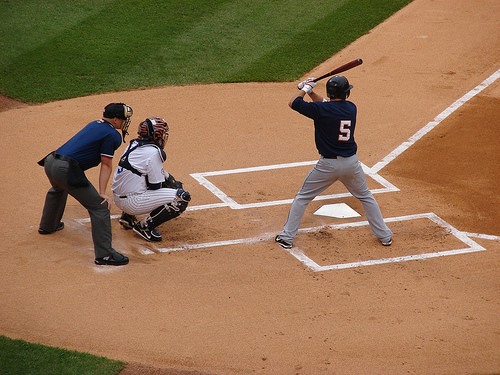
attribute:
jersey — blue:
[290, 96, 359, 159]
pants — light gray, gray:
[279, 152, 394, 247]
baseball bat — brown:
[304, 59, 366, 85]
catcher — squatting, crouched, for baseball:
[111, 114, 192, 244]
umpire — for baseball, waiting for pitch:
[34, 102, 133, 268]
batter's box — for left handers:
[274, 211, 488, 274]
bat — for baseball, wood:
[308, 57, 365, 84]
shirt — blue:
[290, 95, 359, 158]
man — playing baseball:
[35, 102, 132, 268]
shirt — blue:
[56, 117, 123, 171]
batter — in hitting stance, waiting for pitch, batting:
[272, 75, 395, 249]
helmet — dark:
[324, 74, 355, 101]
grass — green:
[0, 336, 132, 375]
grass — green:
[1, 1, 414, 109]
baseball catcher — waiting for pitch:
[111, 116, 191, 242]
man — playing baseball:
[272, 73, 394, 247]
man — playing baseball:
[111, 117, 194, 244]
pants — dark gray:
[37, 151, 113, 259]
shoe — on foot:
[273, 230, 293, 249]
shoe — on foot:
[378, 234, 395, 247]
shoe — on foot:
[118, 210, 138, 230]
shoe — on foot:
[131, 220, 164, 243]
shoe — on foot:
[35, 220, 66, 235]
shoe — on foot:
[92, 250, 131, 267]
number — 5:
[336, 117, 352, 142]